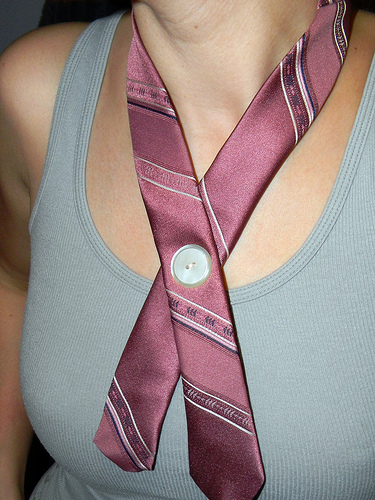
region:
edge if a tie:
[248, 437, 268, 469]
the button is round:
[169, 231, 214, 291]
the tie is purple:
[95, 320, 269, 483]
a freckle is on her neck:
[190, 20, 204, 35]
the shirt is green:
[260, 322, 354, 438]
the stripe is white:
[117, 384, 153, 453]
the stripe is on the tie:
[185, 382, 252, 433]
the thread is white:
[183, 260, 195, 270]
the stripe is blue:
[126, 90, 179, 133]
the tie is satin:
[92, 304, 276, 494]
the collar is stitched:
[291, 257, 307, 269]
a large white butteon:
[167, 236, 212, 290]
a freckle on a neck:
[186, 19, 203, 32]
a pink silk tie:
[85, 81, 329, 490]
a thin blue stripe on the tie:
[107, 402, 111, 415]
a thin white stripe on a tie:
[198, 406, 217, 417]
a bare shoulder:
[4, 21, 79, 144]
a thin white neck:
[126, 4, 317, 89]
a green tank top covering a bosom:
[24, 38, 371, 499]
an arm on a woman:
[0, 293, 31, 496]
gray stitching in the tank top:
[297, 251, 310, 261]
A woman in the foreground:
[1, 1, 373, 492]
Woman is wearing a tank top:
[3, 3, 374, 492]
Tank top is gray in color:
[10, 2, 373, 495]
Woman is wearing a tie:
[57, 1, 373, 498]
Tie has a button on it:
[163, 236, 221, 290]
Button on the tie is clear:
[156, 235, 217, 295]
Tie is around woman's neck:
[94, 0, 367, 148]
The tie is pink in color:
[72, 3, 372, 499]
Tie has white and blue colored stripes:
[90, 15, 343, 478]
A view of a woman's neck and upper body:
[1, 1, 369, 498]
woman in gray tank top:
[2, 2, 373, 498]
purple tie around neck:
[92, 3, 356, 498]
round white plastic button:
[169, 244, 210, 286]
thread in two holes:
[184, 260, 197, 271]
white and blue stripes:
[126, 78, 175, 117]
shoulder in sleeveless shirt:
[0, 24, 89, 247]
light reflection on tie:
[145, 354, 178, 457]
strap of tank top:
[25, 12, 123, 230]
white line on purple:
[182, 395, 253, 440]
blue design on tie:
[168, 296, 233, 336]